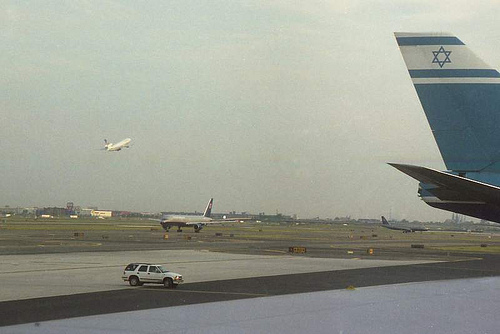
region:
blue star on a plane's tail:
[425, 45, 460, 67]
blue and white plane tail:
[386, 26, 496, 166]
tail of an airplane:
[390, 28, 496, 169]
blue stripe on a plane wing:
[409, 64, 499, 81]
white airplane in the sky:
[96, 132, 138, 153]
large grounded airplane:
[145, 195, 255, 232]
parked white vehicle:
[120, 260, 186, 290]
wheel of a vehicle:
[126, 273, 142, 285]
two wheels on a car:
[127, 273, 177, 288]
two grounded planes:
[141, 195, 433, 234]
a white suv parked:
[121, 258, 186, 285]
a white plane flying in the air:
[109, 133, 129, 154]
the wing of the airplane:
[393, 29, 483, 199]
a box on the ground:
[278, 244, 323, 256]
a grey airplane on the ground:
[383, 209, 431, 235]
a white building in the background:
[67, 195, 115, 220]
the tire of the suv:
[128, 275, 140, 287]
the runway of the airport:
[69, 285, 496, 330]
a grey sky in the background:
[21, 15, 351, 105]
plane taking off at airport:
[97, 131, 137, 156]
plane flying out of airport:
[95, 129, 140, 159]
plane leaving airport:
[102, 136, 142, 151]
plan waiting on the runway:
[147, 190, 247, 235]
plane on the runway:
[148, 192, 256, 241]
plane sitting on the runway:
[375, 207, 443, 247]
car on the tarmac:
[115, 256, 188, 296]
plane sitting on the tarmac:
[147, 198, 243, 235]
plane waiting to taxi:
[139, 195, 254, 242]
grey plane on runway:
[145, 187, 250, 244]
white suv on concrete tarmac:
[115, 255, 185, 293]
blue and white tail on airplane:
[390, 23, 499, 192]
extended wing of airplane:
[388, 150, 498, 209]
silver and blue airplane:
[145, 195, 258, 242]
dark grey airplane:
[376, 210, 436, 242]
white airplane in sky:
[97, 128, 147, 157]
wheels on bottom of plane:
[162, 225, 204, 237]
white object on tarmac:
[363, 241, 377, 258]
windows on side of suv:
[136, 261, 162, 274]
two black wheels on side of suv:
[125, 272, 175, 290]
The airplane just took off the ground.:
[98, 130, 139, 155]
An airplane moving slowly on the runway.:
[135, 190, 251, 235]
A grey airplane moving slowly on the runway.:
[376, 211, 431, 232]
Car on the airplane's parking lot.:
[115, 256, 190, 286]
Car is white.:
[116, 255, 191, 286]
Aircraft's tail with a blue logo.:
[425, 40, 455, 66]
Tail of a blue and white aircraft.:
[390, 25, 490, 225]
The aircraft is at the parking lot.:
[385, 25, 495, 215]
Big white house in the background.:
[76, 205, 116, 220]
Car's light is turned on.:
[170, 270, 181, 280]